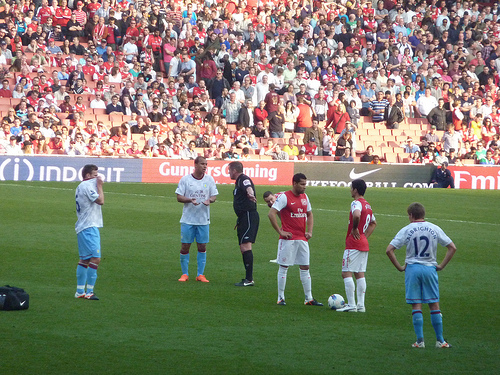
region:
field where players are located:
[3, 182, 495, 367]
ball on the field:
[326, 285, 350, 310]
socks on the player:
[342, 280, 369, 302]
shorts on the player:
[400, 265, 440, 301]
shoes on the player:
[331, 308, 371, 313]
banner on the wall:
[4, 144, 494, 195]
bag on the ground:
[1, 280, 35, 318]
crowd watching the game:
[7, 5, 491, 157]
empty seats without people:
[362, 131, 389, 146]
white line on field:
[438, 213, 493, 231]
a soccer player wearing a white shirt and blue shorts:
[385, 201, 455, 348]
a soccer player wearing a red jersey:
[271, 173, 321, 306]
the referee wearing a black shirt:
[226, 160, 260, 285]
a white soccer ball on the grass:
[326, 291, 346, 309]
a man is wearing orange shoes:
[176, 155, 219, 282]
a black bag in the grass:
[0, 283, 29, 308]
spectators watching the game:
[1, 0, 498, 166]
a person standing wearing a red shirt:
[329, 106, 349, 131]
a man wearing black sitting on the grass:
[428, 163, 455, 188]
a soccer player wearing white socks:
[346, 182, 378, 310]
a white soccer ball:
[326, 292, 347, 308]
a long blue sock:
[407, 305, 423, 340]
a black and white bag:
[0, 280, 30, 310]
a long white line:
[0, 176, 76, 191]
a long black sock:
[240, 245, 250, 276]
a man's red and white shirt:
[270, 185, 310, 240]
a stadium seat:
[367, 125, 373, 132]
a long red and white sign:
[140, 155, 295, 185]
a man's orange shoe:
[191, 275, 206, 280]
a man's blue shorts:
[402, 262, 443, 307]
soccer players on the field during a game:
[63, 150, 453, 350]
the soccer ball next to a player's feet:
[326, 290, 347, 312]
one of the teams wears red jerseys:
[268, 185, 319, 241]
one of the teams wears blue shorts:
[171, 170, 222, 245]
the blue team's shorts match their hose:
[174, 217, 213, 284]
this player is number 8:
[356, 198, 379, 245]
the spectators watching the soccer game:
[2, 0, 498, 152]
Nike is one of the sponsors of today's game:
[342, 163, 389, 185]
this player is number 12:
[405, 229, 437, 264]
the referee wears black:
[225, 158, 265, 289]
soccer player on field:
[176, 157, 214, 284]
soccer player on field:
[70, 165, 103, 301]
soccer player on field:
[269, 173, 320, 313]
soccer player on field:
[338, 178, 370, 310]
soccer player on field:
[386, 201, 458, 352]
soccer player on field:
[264, 190, 282, 208]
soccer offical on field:
[226, 163, 265, 293]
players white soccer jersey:
[388, 220, 450, 267]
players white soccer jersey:
[174, 173, 220, 224]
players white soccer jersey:
[72, 174, 109, 236]